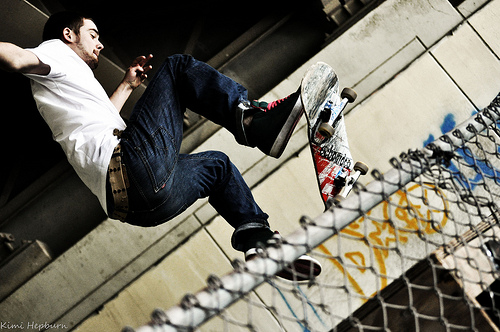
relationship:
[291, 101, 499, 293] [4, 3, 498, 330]
graffiti painted on wall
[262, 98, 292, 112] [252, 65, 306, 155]
shoelaces on shoes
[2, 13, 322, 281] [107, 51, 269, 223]
boy wearing pants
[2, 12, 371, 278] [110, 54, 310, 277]
man wearing blue jeans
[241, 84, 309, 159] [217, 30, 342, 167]
shoe on foot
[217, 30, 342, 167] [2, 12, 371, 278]
foot of man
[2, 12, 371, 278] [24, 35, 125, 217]
man wearing shirt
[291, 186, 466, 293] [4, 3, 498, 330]
graffiti on wall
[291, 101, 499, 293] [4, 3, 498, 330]
graffiti on wall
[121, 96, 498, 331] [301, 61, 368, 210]
fence under skateboard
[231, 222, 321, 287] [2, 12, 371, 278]
left sneaker of a man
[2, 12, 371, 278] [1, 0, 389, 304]
man doing tricks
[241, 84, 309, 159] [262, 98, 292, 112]
shoe with shoelaces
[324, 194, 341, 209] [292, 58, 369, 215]
wheel in skateboard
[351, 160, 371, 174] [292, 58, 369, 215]
wheel in skateboard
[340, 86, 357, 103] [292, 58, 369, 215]
wheel in skateboard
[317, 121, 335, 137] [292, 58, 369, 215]
wheel in skateboard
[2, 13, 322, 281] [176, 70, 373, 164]
boy has a shoe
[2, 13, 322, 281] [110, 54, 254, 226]
boy wearing blue jeans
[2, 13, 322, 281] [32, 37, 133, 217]
boy wearing shirt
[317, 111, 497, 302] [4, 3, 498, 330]
letters on wall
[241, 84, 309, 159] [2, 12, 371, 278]
shoe of man